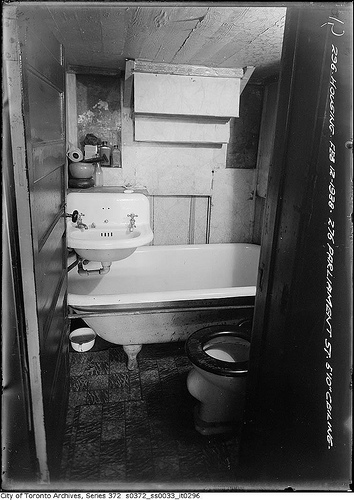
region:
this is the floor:
[78, 376, 115, 470]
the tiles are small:
[99, 398, 163, 458]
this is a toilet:
[174, 325, 258, 430]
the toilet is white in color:
[205, 379, 220, 402]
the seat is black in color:
[189, 337, 202, 356]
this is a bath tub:
[152, 249, 259, 298]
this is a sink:
[69, 191, 152, 276]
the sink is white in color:
[104, 242, 127, 266]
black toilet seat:
[181, 320, 251, 376]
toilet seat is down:
[179, 322, 262, 382]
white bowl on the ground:
[65, 323, 104, 354]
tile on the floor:
[65, 321, 287, 484]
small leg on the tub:
[121, 344, 142, 369]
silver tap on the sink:
[125, 209, 137, 230]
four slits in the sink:
[97, 228, 115, 238]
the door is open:
[2, 3, 97, 486]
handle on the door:
[65, 207, 81, 225]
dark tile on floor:
[83, 362, 110, 375]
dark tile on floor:
[70, 364, 88, 372]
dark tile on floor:
[69, 373, 84, 391]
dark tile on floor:
[86, 376, 107, 387]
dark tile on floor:
[106, 370, 126, 385]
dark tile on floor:
[70, 391, 86, 405]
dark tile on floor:
[105, 387, 128, 401]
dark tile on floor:
[78, 403, 100, 419]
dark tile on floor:
[100, 401, 121, 417]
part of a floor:
[177, 423, 191, 432]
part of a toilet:
[205, 423, 217, 437]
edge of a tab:
[148, 342, 161, 362]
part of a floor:
[149, 440, 152, 444]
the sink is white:
[61, 193, 149, 261]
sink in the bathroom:
[69, 187, 154, 259]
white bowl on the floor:
[63, 323, 96, 354]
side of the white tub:
[64, 274, 253, 312]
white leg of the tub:
[118, 344, 144, 373]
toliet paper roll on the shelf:
[66, 147, 82, 162]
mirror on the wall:
[66, 72, 121, 136]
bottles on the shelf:
[97, 139, 121, 169]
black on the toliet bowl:
[224, 335, 242, 347]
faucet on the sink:
[126, 211, 138, 234]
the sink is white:
[65, 192, 152, 268]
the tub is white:
[66, 241, 263, 370]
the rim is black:
[188, 323, 254, 374]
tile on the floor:
[79, 402, 100, 423]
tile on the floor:
[103, 402, 127, 416]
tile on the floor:
[125, 437, 148, 458]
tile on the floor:
[103, 460, 123, 476]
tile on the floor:
[151, 438, 172, 456]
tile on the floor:
[72, 462, 98, 481]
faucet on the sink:
[128, 212, 138, 226]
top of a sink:
[65, 188, 145, 196]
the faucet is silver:
[74, 210, 88, 229]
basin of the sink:
[66, 228, 139, 241]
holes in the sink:
[99, 232, 113, 236]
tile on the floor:
[87, 349, 110, 360]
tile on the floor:
[109, 372, 127, 385]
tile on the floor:
[104, 402, 122, 416]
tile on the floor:
[75, 439, 96, 456]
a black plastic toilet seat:
[187, 325, 271, 376]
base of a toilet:
[183, 361, 251, 427]